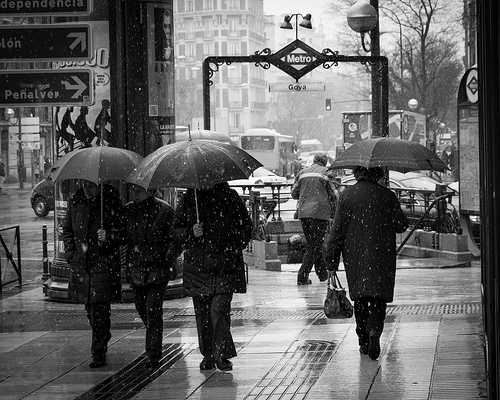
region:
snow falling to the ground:
[167, 247, 263, 296]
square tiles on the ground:
[401, 322, 448, 362]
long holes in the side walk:
[396, 296, 493, 327]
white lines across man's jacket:
[296, 170, 343, 189]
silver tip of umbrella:
[168, 117, 202, 146]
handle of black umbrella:
[184, 178, 209, 245]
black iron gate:
[172, 30, 402, 99]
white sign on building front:
[46, 70, 106, 120]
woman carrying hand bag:
[308, 261, 393, 348]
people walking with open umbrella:
[41, 95, 455, 335]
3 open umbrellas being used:
[29, 130, 450, 178]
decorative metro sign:
[263, 41, 332, 83]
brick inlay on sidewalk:
[240, 339, 344, 396]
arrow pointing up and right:
[63, 25, 85, 54]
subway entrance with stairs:
[257, 222, 456, 271]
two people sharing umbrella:
[40, 145, 189, 385]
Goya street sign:
[270, 82, 332, 94]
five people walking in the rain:
[47, 144, 498, 373]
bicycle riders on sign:
[49, 102, 128, 154]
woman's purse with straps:
[322, 268, 358, 327]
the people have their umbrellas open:
[56, 110, 461, 225]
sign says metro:
[265, 45, 355, 80]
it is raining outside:
[0, 0, 481, 357]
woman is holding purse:
[315, 255, 365, 320]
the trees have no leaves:
[377, 0, 457, 126]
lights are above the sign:
[260, 10, 315, 40]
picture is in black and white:
[1, 0, 497, 396]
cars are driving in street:
[232, 117, 359, 168]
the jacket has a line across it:
[286, 164, 347, 222]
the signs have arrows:
[44, 25, 103, 114]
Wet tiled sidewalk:
[321, 352, 391, 398]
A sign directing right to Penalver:
[3, 70, 90, 102]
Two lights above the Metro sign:
[278, 8, 318, 36]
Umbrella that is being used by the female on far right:
[331, 133, 453, 178]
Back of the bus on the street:
[240, 130, 282, 153]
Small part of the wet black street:
[6, 207, 26, 220]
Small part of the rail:
[416, 203, 440, 220]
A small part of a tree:
[434, 48, 454, 85]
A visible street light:
[320, 70, 332, 115]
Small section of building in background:
[223, 22, 245, 42]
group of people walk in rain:
[34, 100, 269, 377]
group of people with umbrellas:
[35, 126, 277, 398]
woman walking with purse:
[308, 131, 441, 370]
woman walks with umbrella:
[320, 108, 415, 367]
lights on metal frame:
[248, 9, 388, 48]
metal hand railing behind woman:
[380, 179, 468, 259]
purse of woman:
[305, 271, 369, 328]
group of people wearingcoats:
[33, 146, 270, 396]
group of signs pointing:
[4, 22, 136, 106]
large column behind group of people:
[50, 25, 187, 307]